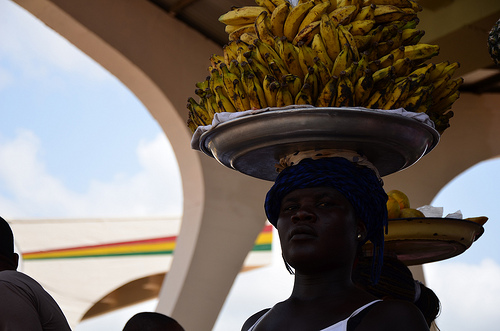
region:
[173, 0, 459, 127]
The bananas on the lady's head.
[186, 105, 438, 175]
The silver tray holding the bananas.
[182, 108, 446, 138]
The cloth under the bananas.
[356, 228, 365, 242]
The earring in the girl's ear.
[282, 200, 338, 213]
The eyes of the girl.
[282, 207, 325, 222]
The nose of the girl.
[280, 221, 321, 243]
The lips of the girl.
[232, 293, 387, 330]
The tank top the girl is wearing.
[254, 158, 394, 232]
The blue scarf wrap on the girl's head.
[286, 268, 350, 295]
The neck area of the girl.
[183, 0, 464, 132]
a bunch of bananas stacked on a plate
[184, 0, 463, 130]
a stack of bananas on a plate that is balancing on top of a woman's head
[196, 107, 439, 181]
round metal plate filled with a stack of bananas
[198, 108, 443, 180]
plate filled with bananas and being balance on the head of a woman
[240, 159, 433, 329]
young woman with a plate of bananas on her head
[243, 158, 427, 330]
woman wearing a white tank top, blue head scarf, and large plate of bananas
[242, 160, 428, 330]
young woman wearing a blue head wrap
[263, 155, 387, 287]
blue cloth head wrap worn by a woman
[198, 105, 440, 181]
metal plate filled with a large amount of bananas resting on the head of a woman wearing a blue head wrap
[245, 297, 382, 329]
white spaghetti string tank top worn by a woman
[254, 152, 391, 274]
The only head of a person fully shown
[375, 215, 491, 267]
The yellow plate in the background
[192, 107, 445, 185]
The large silver plate on a woman's head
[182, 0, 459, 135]
The bananas on the silver platter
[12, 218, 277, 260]
The red, yellow and green flag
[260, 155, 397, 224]
The blue headscarf below the grey platter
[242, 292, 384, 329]
The woman's white tank top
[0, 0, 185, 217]
The clouds on the left side of the photo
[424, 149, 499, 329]
The clouds on the right side of the photo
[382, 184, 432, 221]
The fruit on the yellow platter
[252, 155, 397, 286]
THE WOMAN IS WEARING A BLUE BANDANA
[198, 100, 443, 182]
THE TRAY IS SILVER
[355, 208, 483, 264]
THE TRAY IS YELLOW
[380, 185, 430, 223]
THE PAPAYAS ARE ON THE TRAY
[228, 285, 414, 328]
THIS IS A WHITE TOP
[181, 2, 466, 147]
THESE ARE BANANAS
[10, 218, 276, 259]
THIS IS A RAINBOW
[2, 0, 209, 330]
THIS IS AN ARCHWAY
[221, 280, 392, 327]
THE WOMAN IS WEARING A TANK TOP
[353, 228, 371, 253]
THE WOMAN IS WEARING AN EARRING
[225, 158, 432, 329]
Woman wearing a blue head gear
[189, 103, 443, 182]
Dull white metallic tray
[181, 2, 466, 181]
Heap of ripe bananas carried on a tray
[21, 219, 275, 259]
Long band of three colors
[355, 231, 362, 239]
Small white colored earing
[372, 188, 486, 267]
Yellow tray with some bananas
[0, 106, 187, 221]
Blue sky with some white clouds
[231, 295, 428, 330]
White sleeveless top clothing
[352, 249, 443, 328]
Hair in braids secured by a white band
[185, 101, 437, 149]
Piece of cloth spread inside the tray